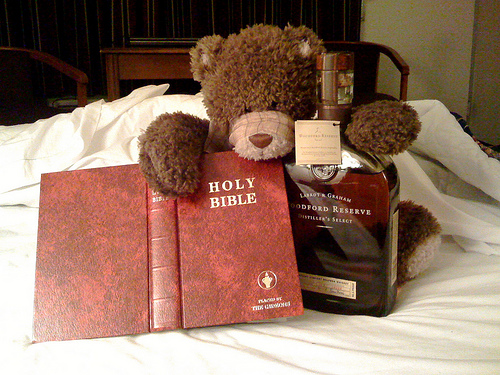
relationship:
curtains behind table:
[323, 8, 359, 86] [97, 34, 379, 104]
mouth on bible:
[251, 148, 274, 158] [33, 149, 305, 342]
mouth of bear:
[251, 148, 274, 158] [137, 22, 442, 287]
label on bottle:
[291, 117, 343, 166] [258, 47, 398, 319]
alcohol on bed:
[263, 51, 400, 316] [1, 80, 493, 372]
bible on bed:
[23, 164, 305, 339] [1, 80, 493, 372]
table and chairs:
[93, 33, 201, 100] [1, 37, 418, 112]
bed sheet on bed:
[0, 85, 494, 370] [1, 80, 493, 372]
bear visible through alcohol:
[137, 22, 442, 287] [283, 45, 405, 315]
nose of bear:
[228, 112, 294, 159] [137, 22, 442, 287]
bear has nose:
[137, 22, 442, 287] [249, 132, 273, 149]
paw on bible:
[132, 122, 214, 194] [26, 142, 306, 341]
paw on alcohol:
[354, 100, 421, 155] [282, 51, 400, 318]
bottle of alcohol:
[282, 51, 400, 316] [282, 51, 400, 318]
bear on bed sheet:
[130, 20, 440, 306] [0, 85, 494, 370]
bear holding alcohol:
[137, 22, 442, 287] [282, 51, 400, 318]